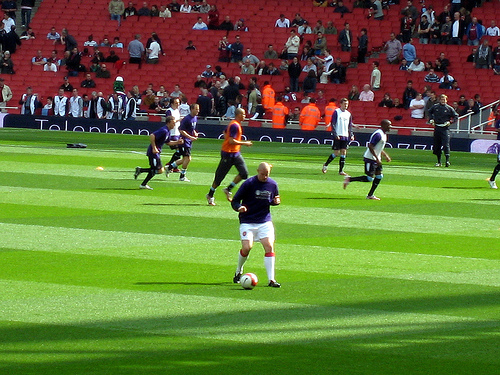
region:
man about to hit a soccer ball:
[231, 164, 281, 291]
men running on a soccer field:
[132, 93, 393, 203]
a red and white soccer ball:
[238, 272, 260, 288]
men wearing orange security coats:
[260, 85, 336, 129]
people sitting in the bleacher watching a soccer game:
[0, 1, 499, 118]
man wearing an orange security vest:
[221, 120, 242, 153]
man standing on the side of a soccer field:
[428, 94, 458, 170]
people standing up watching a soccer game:
[18, 85, 138, 120]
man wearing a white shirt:
[3, 15, 15, 30]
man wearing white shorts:
[241, 221, 275, 237]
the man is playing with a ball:
[233, 155, 326, 317]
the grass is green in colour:
[24, 210, 146, 354]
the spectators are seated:
[60, 15, 365, 119]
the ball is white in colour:
[218, 255, 278, 292]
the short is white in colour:
[230, 222, 286, 242]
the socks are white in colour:
[243, 246, 287, 295]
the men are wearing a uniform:
[130, 79, 414, 184]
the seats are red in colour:
[122, 6, 341, 106]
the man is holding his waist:
[417, 79, 478, 175]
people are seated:
[194, 6, 411, 115]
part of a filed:
[315, 280, 347, 330]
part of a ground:
[364, 258, 400, 308]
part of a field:
[363, 227, 390, 272]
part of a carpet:
[348, 218, 383, 270]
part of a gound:
[341, 222, 376, 274]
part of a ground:
[358, 265, 387, 305]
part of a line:
[346, 238, 366, 260]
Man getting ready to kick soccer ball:
[221, 157, 291, 309]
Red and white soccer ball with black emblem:
[234, 269, 258, 298]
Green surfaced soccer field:
[0, 130, 499, 373]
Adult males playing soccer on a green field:
[66, 85, 405, 310]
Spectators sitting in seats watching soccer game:
[3, 0, 498, 142]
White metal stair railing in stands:
[442, 91, 495, 136]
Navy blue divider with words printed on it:
[1, 103, 498, 150]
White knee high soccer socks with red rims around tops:
[230, 244, 280, 281]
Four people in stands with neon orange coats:
[251, 80, 346, 132]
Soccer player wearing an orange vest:
[201, 105, 263, 213]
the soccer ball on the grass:
[238, 272, 258, 289]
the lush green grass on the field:
[0, 126, 498, 373]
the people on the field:
[135, 94, 499, 288]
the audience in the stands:
[0, 0, 499, 139]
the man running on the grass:
[342, 117, 391, 199]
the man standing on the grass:
[425, 93, 457, 168]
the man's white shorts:
[240, 220, 275, 240]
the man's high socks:
[235, 248, 275, 281]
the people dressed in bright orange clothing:
[259, 79, 337, 132]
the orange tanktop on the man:
[222, 117, 242, 151]